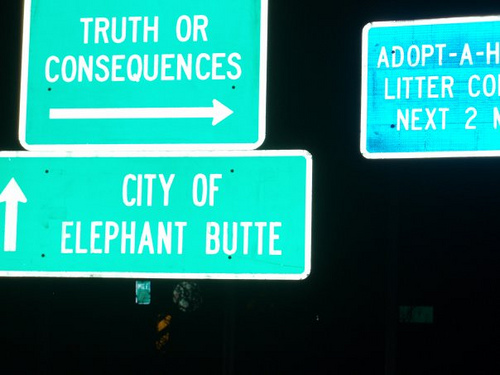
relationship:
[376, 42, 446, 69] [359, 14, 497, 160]
word adopt on sign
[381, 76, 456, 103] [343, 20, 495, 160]
litter on sign